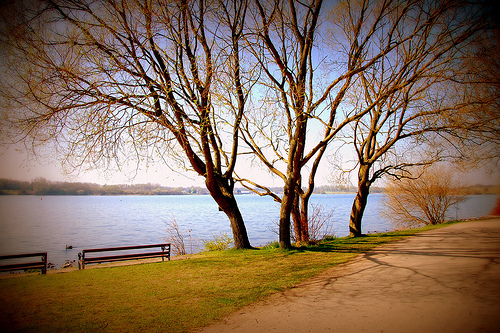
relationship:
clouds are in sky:
[2, 95, 494, 182] [2, 2, 498, 185]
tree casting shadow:
[230, 3, 352, 255] [348, 235, 450, 283]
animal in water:
[65, 243, 73, 249] [7, 167, 489, 254]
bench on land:
[73, 239, 170, 269] [0, 217, 497, 333]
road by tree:
[196, 215, 498, 331] [0, 0, 264, 250]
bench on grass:
[1, 250, 48, 275] [0, 215, 499, 330]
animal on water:
[65, 243, 73, 249] [108, 161, 229, 225]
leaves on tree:
[54, 27, 94, 61] [0, 0, 264, 250]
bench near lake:
[77, 239, 170, 269] [0, 190, 500, 266]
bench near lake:
[1, 250, 48, 275] [0, 190, 500, 266]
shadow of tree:
[363, 239, 425, 275] [208, 72, 412, 230]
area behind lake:
[86, 127, 320, 217] [10, 171, 486, 239]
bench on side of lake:
[1, 251, 47, 275] [54, 195, 178, 232]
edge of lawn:
[204, 295, 264, 331] [0, 214, 495, 331]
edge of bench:
[65, 246, 167, 273] [54, 218, 208, 283]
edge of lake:
[80, 180, 172, 199] [0, 190, 500, 266]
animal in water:
[38, 220, 70, 259] [163, 192, 296, 239]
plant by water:
[216, 256, 293, 275] [188, 232, 236, 264]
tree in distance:
[223, 0, 353, 255] [22, 168, 249, 204]